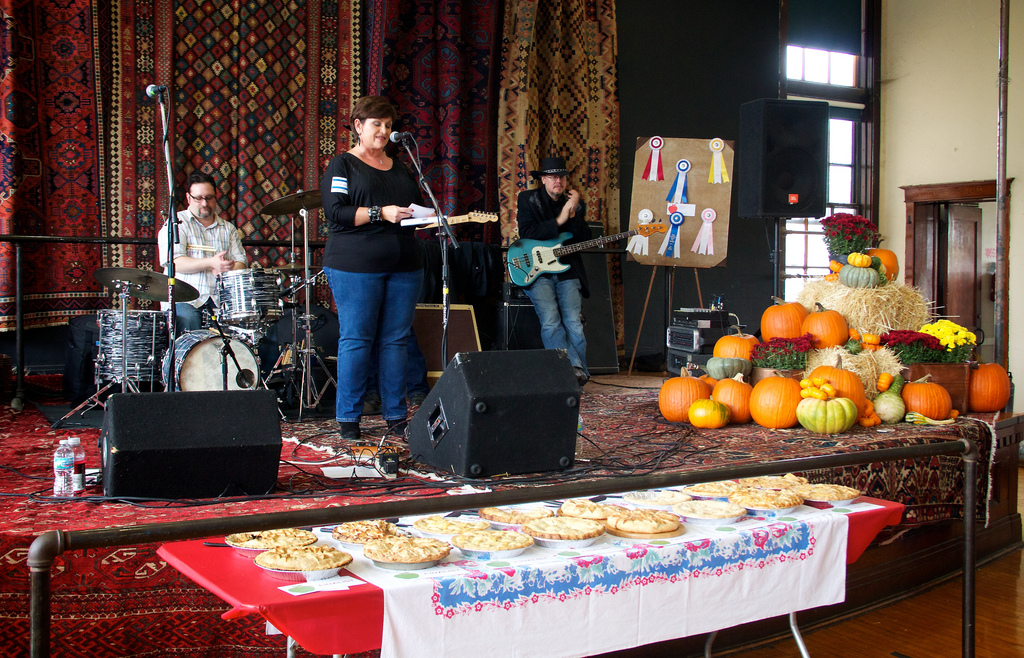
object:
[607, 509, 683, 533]
food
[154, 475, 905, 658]
table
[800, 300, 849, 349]
pumpkins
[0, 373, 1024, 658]
stage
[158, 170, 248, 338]
man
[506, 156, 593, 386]
person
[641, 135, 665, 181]
ribbons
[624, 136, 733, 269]
board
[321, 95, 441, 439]
people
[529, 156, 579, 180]
hat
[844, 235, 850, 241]
flowers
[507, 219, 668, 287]
guitar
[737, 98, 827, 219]
speakers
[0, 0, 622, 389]
curtain